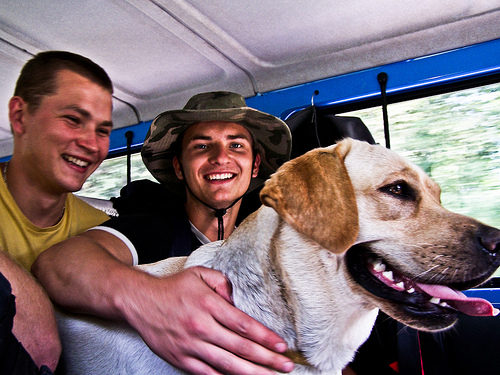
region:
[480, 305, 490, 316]
Red tomato on top of a bunch of lettuce.Red tomato on top of a bunch of lettuce.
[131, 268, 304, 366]
the mans hand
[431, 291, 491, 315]
the tongue of the dog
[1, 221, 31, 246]
man is wearing a yellow shirt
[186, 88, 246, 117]
the man is wearing a hat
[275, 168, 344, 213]
the dogs ear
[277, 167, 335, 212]
the dogs ear is brown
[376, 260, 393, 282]
the dogs teeth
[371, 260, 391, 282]
the dogs teeth are white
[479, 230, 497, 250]
the dogs nose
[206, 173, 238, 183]
the man is smiling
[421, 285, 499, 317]
the tongue of a dog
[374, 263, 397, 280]
the teeth of a dog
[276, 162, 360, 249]
the ear of a dog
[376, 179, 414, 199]
the eye of a dog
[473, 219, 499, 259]
the nose of a dog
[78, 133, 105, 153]
the nose of a man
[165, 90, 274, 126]
a cap on a man's head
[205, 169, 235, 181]
the teeth of a man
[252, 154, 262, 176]
the ear of a man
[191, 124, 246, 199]
the face of a man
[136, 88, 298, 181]
a floppy camo hat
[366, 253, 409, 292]
a few sharp teeth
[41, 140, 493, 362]
a happy golden retriever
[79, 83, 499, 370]
a man with his arm around a dog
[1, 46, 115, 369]
a man in a yellow shirt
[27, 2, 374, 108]
some grey ceiling panels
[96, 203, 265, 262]
a black and white t-shirt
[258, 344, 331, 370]
a yellow dog collar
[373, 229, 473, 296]
a few white whiskers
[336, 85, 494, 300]
a bus window